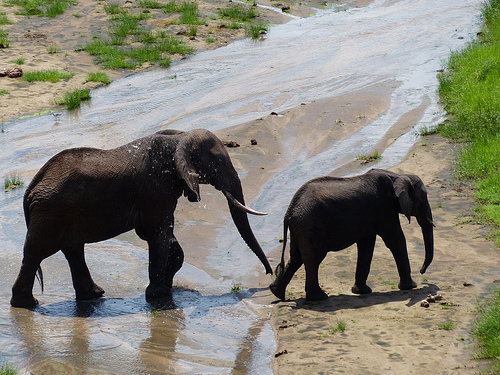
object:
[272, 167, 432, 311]
animal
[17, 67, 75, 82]
grass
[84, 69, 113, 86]
grass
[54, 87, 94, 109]
grass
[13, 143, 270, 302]
animal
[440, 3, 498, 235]
grass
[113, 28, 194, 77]
grass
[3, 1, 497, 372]
field